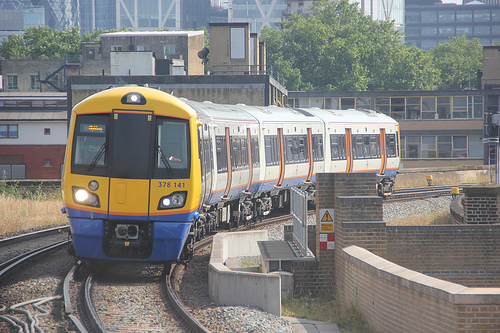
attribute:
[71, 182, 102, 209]
light — on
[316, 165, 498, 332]
wall — brick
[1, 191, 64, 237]
grass — brown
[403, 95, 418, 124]
window — small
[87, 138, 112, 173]
wiper — black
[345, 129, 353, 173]
door — orange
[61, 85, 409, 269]
train — turning, yellow, blue, white, moving, passenger, numbered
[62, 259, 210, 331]
tracks — gravel, curvy